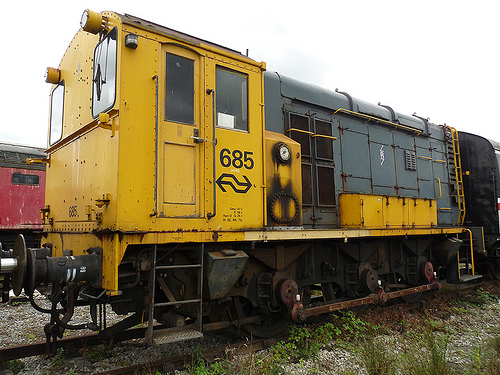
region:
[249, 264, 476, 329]
train's wheels are rusty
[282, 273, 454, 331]
train's wheels are rusty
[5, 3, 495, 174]
bright sky above red and yellow trains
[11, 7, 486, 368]
yellow and black train engine on tracks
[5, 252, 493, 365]
gravel and green weeds on side of engine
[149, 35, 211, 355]
windowed door over short ladder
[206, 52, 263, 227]
black numbers and black symbol under window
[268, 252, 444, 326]
three metal wheels connected with bar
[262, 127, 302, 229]
yellow panel with black ring and measuring tool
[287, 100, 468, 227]
yellow bars and ladder across black engine section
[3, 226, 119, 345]
large and dark plugs on front of train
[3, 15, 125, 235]
yellow train in front of red train with black roof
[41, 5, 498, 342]
Black and yellow train on a track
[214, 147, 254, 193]
Black numbers on yellow train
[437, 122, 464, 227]
Yellow ladder on train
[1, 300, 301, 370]
Train tracks on the ground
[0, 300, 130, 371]
Gravel next to the train track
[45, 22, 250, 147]
Glass windows on the train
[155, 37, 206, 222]
Door into the yellow train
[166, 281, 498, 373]
Green foliage on the ground next to the track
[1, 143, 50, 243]
Red train behind the yellow train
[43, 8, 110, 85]
Lights on the yellow train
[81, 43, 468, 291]
A yellow and black train.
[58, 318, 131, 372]
The tracks are rusty.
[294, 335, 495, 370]
Rocks on the ground.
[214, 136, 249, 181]
Number 685 on the train.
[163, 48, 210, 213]
The door of the train engine.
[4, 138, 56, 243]
A red train next to the yellow train.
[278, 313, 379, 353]
Little flowers on the ground.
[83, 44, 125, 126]
Window on front of train.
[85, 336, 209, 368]
Gravel and rocks under the train.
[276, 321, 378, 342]
Bushes along side of the track.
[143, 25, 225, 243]
the door is yellow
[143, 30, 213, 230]
the door is closed